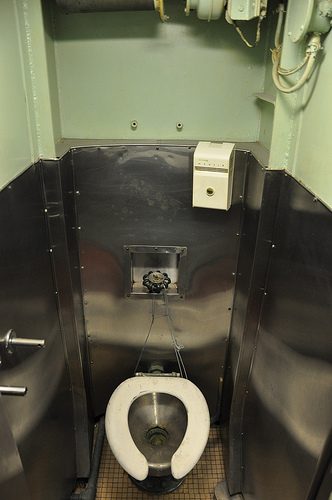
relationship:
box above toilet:
[192, 134, 235, 214] [105, 373, 211, 494]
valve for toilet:
[142, 270, 171, 293] [96, 365, 206, 436]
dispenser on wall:
[172, 138, 268, 212] [100, 38, 301, 315]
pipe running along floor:
[74, 415, 105, 499] [70, 420, 223, 497]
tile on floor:
[193, 492, 199, 497] [70, 420, 223, 497]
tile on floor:
[111, 491, 118, 497] [70, 420, 223, 497]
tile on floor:
[202, 477, 209, 483] [70, 420, 223, 497]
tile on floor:
[108, 471, 115, 477] [70, 420, 223, 497]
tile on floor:
[208, 453, 216, 460] [70, 420, 223, 497]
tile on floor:
[180, 454, 230, 486] [70, 420, 223, 497]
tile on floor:
[191, 465, 217, 495] [70, 420, 223, 497]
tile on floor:
[101, 466, 230, 496] [70, 420, 223, 497]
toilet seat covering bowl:
[103, 369, 210, 479] [127, 391, 188, 468]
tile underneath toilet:
[72, 422, 228, 499] [100, 369, 216, 495]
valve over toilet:
[141, 269, 171, 292] [100, 369, 216, 495]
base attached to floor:
[124, 473, 190, 499] [95, 425, 224, 496]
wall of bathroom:
[1, 137, 330, 498] [1, 0, 331, 498]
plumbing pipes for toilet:
[271, 8, 326, 91] [103, 359, 212, 498]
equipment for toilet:
[101, 221, 186, 378] [103, 359, 212, 498]